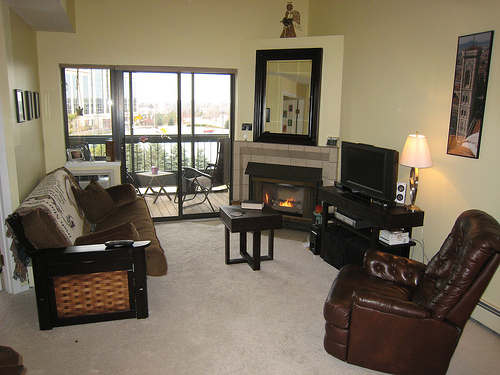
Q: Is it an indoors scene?
A: Yes, it is indoors.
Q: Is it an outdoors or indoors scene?
A: It is indoors.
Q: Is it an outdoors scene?
A: No, it is indoors.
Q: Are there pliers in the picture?
A: No, there are no pliers.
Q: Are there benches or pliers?
A: No, there are no pliers or benches.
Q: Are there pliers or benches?
A: No, there are no pliers or benches.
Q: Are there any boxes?
A: No, there are no boxes.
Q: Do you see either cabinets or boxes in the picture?
A: No, there are no boxes or cabinets.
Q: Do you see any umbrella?
A: No, there are no umbrellas.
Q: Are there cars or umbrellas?
A: No, there are no umbrellas or cars.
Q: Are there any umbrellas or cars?
A: No, there are no umbrellas or cars.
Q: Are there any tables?
A: Yes, there is a table.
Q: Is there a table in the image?
A: Yes, there is a table.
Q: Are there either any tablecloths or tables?
A: Yes, there is a table.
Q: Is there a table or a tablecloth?
A: Yes, there is a table.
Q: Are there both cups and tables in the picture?
A: No, there is a table but no cups.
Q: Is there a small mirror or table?
A: Yes, there is a small table.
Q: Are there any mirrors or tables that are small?
A: Yes, the table is small.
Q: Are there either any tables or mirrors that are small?
A: Yes, the table is small.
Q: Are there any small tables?
A: Yes, there is a small table.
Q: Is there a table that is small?
A: Yes, there is a table that is small.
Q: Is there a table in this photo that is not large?
A: Yes, there is a small table.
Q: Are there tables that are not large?
A: Yes, there is a small table.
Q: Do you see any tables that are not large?
A: Yes, there is a small table.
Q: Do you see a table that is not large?
A: Yes, there is a small table.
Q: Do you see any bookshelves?
A: No, there are no bookshelves.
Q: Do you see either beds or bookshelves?
A: No, there are no bookshelves or beds.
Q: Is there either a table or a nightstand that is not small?
A: No, there is a table but it is small.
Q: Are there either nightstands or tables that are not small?
A: No, there is a table but it is small.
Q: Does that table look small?
A: Yes, the table is small.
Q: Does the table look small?
A: Yes, the table is small.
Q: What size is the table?
A: The table is small.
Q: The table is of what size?
A: The table is small.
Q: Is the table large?
A: No, the table is small.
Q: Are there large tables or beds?
A: No, there is a table but it is small.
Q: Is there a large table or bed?
A: No, there is a table but it is small.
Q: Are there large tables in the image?
A: No, there is a table but it is small.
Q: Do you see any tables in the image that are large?
A: No, there is a table but it is small.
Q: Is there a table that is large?
A: No, there is a table but it is small.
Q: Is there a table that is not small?
A: No, there is a table but it is small.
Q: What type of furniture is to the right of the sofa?
A: The piece of furniture is a table.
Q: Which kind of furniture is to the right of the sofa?
A: The piece of furniture is a table.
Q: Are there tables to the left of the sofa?
A: No, the table is to the right of the sofa.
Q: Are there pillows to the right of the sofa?
A: No, there is a table to the right of the sofa.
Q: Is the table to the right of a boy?
A: No, the table is to the right of the sofa.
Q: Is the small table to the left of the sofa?
A: No, the table is to the right of the sofa.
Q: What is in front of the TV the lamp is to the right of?
A: The table is in front of the TV.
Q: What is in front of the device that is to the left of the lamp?
A: The table is in front of the TV.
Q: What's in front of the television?
A: The table is in front of the TV.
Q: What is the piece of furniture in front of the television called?
A: The piece of furniture is a table.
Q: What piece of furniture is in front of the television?
A: The piece of furniture is a table.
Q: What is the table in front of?
A: The table is in front of the television.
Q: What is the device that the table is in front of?
A: The device is a television.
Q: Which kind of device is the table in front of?
A: The table is in front of the TV.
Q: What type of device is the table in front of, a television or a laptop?
A: The table is in front of a television.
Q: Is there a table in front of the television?
A: Yes, there is a table in front of the television.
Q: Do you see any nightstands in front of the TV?
A: No, there is a table in front of the TV.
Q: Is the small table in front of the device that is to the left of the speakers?
A: Yes, the table is in front of the TV.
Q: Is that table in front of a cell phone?
A: No, the table is in front of the TV.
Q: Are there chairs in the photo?
A: Yes, there is a chair.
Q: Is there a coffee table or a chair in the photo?
A: Yes, there is a chair.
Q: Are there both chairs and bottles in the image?
A: No, there is a chair but no bottles.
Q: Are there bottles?
A: No, there are no bottles.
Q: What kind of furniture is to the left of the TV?
A: The piece of furniture is a chair.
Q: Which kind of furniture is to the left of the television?
A: The piece of furniture is a chair.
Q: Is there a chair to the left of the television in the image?
A: Yes, there is a chair to the left of the television.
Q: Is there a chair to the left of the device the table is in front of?
A: Yes, there is a chair to the left of the television.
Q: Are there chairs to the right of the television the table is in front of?
A: No, the chair is to the left of the television.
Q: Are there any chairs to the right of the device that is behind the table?
A: No, the chair is to the left of the television.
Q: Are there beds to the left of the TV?
A: No, there is a chair to the left of the TV.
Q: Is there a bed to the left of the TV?
A: No, there is a chair to the left of the TV.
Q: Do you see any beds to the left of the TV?
A: No, there is a chair to the left of the TV.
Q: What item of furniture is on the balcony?
A: The piece of furniture is a chair.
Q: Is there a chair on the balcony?
A: Yes, there is a chair on the balcony.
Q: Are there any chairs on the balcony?
A: Yes, there is a chair on the balcony.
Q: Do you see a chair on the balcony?
A: Yes, there is a chair on the balcony.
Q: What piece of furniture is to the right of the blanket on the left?
A: The piece of furniture is a chair.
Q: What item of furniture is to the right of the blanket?
A: The piece of furniture is a chair.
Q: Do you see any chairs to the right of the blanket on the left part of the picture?
A: Yes, there is a chair to the right of the blanket.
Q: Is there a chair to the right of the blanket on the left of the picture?
A: Yes, there is a chair to the right of the blanket.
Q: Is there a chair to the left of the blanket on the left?
A: No, the chair is to the right of the blanket.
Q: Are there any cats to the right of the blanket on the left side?
A: No, there is a chair to the right of the blanket.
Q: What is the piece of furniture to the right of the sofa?
A: The piece of furniture is a chair.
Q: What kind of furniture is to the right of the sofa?
A: The piece of furniture is a chair.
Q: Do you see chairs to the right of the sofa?
A: Yes, there is a chair to the right of the sofa.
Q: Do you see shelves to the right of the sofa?
A: No, there is a chair to the right of the sofa.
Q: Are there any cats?
A: No, there are no cats.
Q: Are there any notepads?
A: No, there are no notepads.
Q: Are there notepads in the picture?
A: No, there are no notepads.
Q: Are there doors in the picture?
A: Yes, there is a door.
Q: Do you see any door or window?
A: Yes, there is a door.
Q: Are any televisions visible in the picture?
A: Yes, there is a television.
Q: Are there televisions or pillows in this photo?
A: Yes, there is a television.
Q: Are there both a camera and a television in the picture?
A: No, there is a television but no cameras.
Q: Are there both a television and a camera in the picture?
A: No, there is a television but no cameras.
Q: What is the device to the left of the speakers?
A: The device is a television.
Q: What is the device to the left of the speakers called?
A: The device is a television.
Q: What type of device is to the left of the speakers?
A: The device is a television.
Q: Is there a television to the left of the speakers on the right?
A: Yes, there is a television to the left of the speakers.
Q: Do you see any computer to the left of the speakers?
A: No, there is a television to the left of the speakers.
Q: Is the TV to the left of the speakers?
A: Yes, the TV is to the left of the speakers.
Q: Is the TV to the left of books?
A: No, the TV is to the left of the speakers.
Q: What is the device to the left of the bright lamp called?
A: The device is a television.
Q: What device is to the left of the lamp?
A: The device is a television.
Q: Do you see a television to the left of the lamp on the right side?
A: Yes, there is a television to the left of the lamp.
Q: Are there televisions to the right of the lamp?
A: No, the television is to the left of the lamp.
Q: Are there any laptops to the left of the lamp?
A: No, there is a television to the left of the lamp.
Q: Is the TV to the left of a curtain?
A: No, the TV is to the left of a lamp.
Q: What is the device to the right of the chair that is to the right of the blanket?
A: The device is a television.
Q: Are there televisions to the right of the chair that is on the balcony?
A: Yes, there is a television to the right of the chair.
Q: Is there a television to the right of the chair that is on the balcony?
A: Yes, there is a television to the right of the chair.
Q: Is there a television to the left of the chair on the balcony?
A: No, the television is to the right of the chair.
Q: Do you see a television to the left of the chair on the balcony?
A: No, the television is to the right of the chair.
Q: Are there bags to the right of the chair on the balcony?
A: No, there is a television to the right of the chair.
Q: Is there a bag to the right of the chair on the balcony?
A: No, there is a television to the right of the chair.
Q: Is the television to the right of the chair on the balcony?
A: Yes, the television is to the right of the chair.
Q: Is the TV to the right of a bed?
A: No, the TV is to the right of the chair.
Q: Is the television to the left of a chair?
A: No, the television is to the right of a chair.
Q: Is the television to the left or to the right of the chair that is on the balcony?
A: The television is to the right of the chair.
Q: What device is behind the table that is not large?
A: The device is a television.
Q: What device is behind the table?
A: The device is a television.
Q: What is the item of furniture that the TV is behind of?
A: The piece of furniture is a table.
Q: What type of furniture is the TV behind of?
A: The TV is behind the table.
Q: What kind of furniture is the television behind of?
A: The TV is behind the table.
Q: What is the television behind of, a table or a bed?
A: The television is behind a table.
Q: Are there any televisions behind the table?
A: Yes, there is a television behind the table.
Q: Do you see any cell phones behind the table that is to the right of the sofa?
A: No, there is a television behind the table.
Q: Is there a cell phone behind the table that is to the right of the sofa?
A: No, there is a television behind the table.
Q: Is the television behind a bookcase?
A: No, the television is behind the table.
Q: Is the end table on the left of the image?
A: Yes, the end table is on the left of the image.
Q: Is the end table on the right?
A: No, the end table is on the left of the image.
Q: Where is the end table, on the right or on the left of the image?
A: The end table is on the left of the image.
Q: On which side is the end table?
A: The end table is on the left of the image.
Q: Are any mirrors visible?
A: Yes, there is a mirror.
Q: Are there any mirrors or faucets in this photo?
A: Yes, there is a mirror.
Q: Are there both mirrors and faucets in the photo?
A: No, there is a mirror but no faucets.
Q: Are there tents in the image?
A: No, there are no tents.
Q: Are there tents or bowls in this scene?
A: No, there are no tents or bowls.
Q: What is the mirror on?
A: The mirror is on the wall.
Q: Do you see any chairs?
A: Yes, there is a chair.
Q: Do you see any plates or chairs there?
A: Yes, there is a chair.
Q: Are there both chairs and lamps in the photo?
A: Yes, there are both a chair and a lamp.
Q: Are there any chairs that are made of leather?
A: Yes, there is a chair that is made of leather.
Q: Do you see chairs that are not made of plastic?
A: Yes, there is a chair that is made of leather.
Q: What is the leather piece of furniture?
A: The piece of furniture is a chair.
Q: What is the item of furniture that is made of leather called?
A: The piece of furniture is a chair.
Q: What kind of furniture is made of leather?
A: The furniture is a chair.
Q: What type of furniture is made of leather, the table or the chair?
A: The chair is made of leather.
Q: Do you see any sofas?
A: Yes, there is a sofa.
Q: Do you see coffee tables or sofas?
A: Yes, there is a sofa.